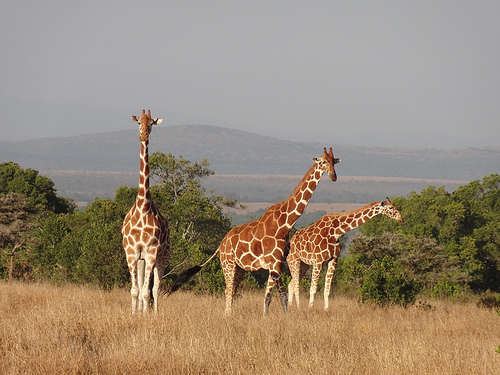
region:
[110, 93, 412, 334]
Three animals in the foreground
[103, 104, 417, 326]
The animals are african giraffes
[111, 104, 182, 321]
A front view of an african giraffe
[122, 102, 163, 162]
Giraffe is looking at the camera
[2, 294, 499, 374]
The grass is dried out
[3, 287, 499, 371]
The grass is tan colored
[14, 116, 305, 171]
A small mountain in the background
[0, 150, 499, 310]
Tall trees in the background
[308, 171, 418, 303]
Giraffes head is lowered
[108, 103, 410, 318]
Animal's have brown colored spots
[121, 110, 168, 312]
Giraffe looking at the camera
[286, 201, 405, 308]
Giraffe eating tree leaves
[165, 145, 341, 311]
Giraffe walking in the field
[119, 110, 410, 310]
Three giraffes in the wild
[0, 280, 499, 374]
Tall brown dry grass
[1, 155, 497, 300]
Trees behind the giraffes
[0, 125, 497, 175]
Mountain in the background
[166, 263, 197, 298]
Black tip of giraffes tail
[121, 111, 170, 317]
Giraffe standing on grassland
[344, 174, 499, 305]
Thick bushes in grassland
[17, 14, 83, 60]
white clouds in blue sky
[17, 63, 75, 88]
white clouds in blue sky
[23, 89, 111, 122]
white clouds in blue sky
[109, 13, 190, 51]
white clouds in blue sky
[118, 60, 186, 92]
white clouds in blue sky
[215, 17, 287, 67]
white clouds in blue sky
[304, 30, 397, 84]
white clouds in blue sky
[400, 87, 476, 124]
white clouds in blue sky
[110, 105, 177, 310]
tan and brown giraffe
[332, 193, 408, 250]
tan and brown giraffe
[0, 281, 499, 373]
Field of brown grass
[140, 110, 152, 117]
Horns on a giraffe's head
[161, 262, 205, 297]
Black hair on a giraffe's tail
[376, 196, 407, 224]
Giraffe's head facing right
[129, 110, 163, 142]
Giraffe's head facing forward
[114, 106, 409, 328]
Three giraffes in the grass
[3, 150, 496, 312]
Trees behind giraffes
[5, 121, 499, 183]
Mountains behind three giraffes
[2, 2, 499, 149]
Grey sky above giraffes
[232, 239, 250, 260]
Brown spot on a giraffe's body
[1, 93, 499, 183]
the mountains in the distance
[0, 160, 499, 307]
the green trees behind the giraffes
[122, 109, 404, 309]
the three giraffes standing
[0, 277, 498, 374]
the tall brown grass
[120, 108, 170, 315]
the giraffe on the left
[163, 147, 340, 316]
the giraffe in the middle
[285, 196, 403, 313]
the giraffe on the right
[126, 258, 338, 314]
the legs on the giraffes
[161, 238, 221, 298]
the tail on the middle giraffe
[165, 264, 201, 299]
the black hair at the end of the tail